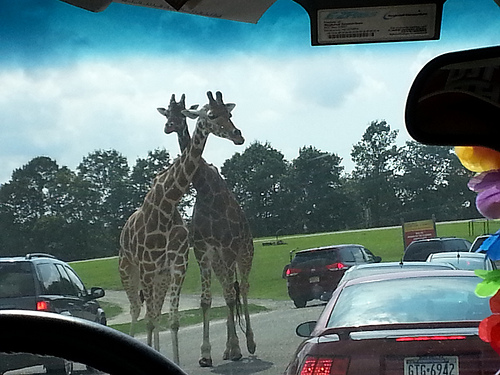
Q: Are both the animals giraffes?
A: Yes, all the animals are giraffes.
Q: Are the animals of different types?
A: No, all the animals are giraffes.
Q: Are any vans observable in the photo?
A: No, there are no vans.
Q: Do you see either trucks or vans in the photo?
A: No, there are no vans or trucks.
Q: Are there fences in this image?
A: No, there are no fences.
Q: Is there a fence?
A: No, there are no fences.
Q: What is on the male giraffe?
A: The spots are on the giraffe.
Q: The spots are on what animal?
A: The spots are on the giraffe.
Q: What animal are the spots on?
A: The spots are on the giraffe.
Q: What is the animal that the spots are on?
A: The animal is a giraffe.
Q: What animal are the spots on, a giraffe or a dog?
A: The spots are on a giraffe.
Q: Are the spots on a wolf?
A: No, the spots are on the giraffe.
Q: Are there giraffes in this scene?
A: Yes, there is a giraffe.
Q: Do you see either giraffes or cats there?
A: Yes, there is a giraffe.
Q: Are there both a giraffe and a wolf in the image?
A: No, there is a giraffe but no wolves.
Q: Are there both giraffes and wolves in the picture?
A: No, there is a giraffe but no wolves.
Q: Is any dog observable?
A: No, there are no dogs.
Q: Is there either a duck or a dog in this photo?
A: No, there are no dogs or ducks.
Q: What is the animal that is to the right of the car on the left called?
A: The animal is a giraffe.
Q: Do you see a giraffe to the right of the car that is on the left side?
A: Yes, there is a giraffe to the right of the car.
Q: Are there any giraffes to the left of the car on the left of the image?
A: No, the giraffe is to the right of the car.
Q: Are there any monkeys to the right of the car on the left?
A: No, there is a giraffe to the right of the car.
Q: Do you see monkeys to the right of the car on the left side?
A: No, there is a giraffe to the right of the car.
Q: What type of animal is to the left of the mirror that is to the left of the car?
A: The animal is a giraffe.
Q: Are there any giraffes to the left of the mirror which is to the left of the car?
A: Yes, there is a giraffe to the left of the mirror.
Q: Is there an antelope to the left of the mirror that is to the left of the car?
A: No, there is a giraffe to the left of the mirror.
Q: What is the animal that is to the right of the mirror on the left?
A: The animal is a giraffe.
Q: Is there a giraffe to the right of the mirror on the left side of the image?
A: Yes, there is a giraffe to the right of the mirror.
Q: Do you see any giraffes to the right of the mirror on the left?
A: Yes, there is a giraffe to the right of the mirror.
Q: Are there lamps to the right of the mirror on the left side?
A: No, there is a giraffe to the right of the mirror.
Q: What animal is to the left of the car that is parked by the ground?
A: The animal is a giraffe.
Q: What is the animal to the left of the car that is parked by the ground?
A: The animal is a giraffe.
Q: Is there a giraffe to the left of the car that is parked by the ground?
A: Yes, there is a giraffe to the left of the car.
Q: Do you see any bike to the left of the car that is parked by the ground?
A: No, there is a giraffe to the left of the car.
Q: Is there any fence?
A: No, there are no fences.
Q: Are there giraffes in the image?
A: Yes, there is a giraffe.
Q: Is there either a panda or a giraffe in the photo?
A: Yes, there is a giraffe.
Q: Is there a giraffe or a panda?
A: Yes, there is a giraffe.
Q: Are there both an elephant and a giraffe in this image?
A: No, there is a giraffe but no elephants.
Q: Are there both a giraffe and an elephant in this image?
A: No, there is a giraffe but no elephants.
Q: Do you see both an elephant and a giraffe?
A: No, there is a giraffe but no elephants.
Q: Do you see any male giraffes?
A: Yes, there is a male giraffe.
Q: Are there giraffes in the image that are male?
A: Yes, there is a giraffe that is male.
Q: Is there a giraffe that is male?
A: Yes, there is a giraffe that is male.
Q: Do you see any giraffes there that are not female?
A: Yes, there is a male giraffe.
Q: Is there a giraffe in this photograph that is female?
A: Yes, there is a female giraffe.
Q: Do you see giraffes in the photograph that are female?
A: Yes, there is a giraffe that is female.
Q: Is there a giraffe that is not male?
A: Yes, there is a female giraffe.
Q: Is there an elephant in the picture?
A: No, there are no elephants.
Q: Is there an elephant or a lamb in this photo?
A: No, there are no elephants or lambs.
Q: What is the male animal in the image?
A: The animal is a giraffe.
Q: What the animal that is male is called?
A: The animal is a giraffe.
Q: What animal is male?
A: The animal is a giraffe.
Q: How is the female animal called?
A: The animal is a giraffe.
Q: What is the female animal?
A: The animal is a giraffe.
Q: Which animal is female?
A: The animal is a giraffe.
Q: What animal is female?
A: The animal is a giraffe.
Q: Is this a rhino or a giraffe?
A: This is a giraffe.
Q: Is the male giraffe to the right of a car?
A: No, the giraffe is to the left of a car.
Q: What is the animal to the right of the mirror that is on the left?
A: The animal is a giraffe.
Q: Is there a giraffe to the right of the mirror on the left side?
A: Yes, there is a giraffe to the right of the mirror.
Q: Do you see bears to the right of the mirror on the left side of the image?
A: No, there is a giraffe to the right of the mirror.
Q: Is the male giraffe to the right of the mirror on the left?
A: Yes, the giraffe is to the right of the mirror.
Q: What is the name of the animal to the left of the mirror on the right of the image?
A: The animal is a giraffe.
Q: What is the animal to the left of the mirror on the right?
A: The animal is a giraffe.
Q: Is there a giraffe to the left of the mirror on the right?
A: Yes, there is a giraffe to the left of the mirror.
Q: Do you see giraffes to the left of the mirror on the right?
A: Yes, there is a giraffe to the left of the mirror.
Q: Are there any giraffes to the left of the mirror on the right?
A: Yes, there is a giraffe to the left of the mirror.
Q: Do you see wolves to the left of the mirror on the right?
A: No, there is a giraffe to the left of the mirror.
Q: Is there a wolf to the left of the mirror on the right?
A: No, there is a giraffe to the left of the mirror.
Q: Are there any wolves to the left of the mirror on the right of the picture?
A: No, there is a giraffe to the left of the mirror.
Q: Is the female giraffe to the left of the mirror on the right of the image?
A: Yes, the giraffe is to the left of the mirror.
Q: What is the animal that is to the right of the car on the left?
A: The animal is a giraffe.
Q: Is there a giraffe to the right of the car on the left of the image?
A: Yes, there is a giraffe to the right of the car.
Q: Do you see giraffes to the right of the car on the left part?
A: Yes, there is a giraffe to the right of the car.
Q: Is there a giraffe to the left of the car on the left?
A: No, the giraffe is to the right of the car.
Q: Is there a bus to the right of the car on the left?
A: No, there is a giraffe to the right of the car.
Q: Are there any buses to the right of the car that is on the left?
A: No, there is a giraffe to the right of the car.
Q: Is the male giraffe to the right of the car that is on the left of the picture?
A: Yes, the giraffe is to the right of the car.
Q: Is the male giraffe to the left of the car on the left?
A: No, the giraffe is to the right of the car.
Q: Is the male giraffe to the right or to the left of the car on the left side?
A: The giraffe is to the right of the car.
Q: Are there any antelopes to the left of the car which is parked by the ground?
A: No, there is a giraffe to the left of the car.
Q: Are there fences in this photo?
A: No, there are no fences.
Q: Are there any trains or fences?
A: No, there are no fences or trains.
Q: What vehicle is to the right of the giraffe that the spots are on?
A: The vehicle is a car.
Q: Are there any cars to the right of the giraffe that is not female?
A: Yes, there is a car to the right of the giraffe.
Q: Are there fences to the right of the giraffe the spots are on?
A: No, there is a car to the right of the giraffe.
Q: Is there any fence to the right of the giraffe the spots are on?
A: No, there is a car to the right of the giraffe.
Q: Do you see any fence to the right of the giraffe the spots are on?
A: No, there is a car to the right of the giraffe.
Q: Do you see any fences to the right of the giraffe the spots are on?
A: No, there is a car to the right of the giraffe.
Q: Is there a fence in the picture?
A: No, there are no fences.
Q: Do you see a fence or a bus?
A: No, there are no fences or buses.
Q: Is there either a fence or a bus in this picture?
A: No, there are no fences or buses.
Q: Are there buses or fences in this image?
A: No, there are no fences or buses.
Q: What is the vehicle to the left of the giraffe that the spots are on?
A: The vehicle is a car.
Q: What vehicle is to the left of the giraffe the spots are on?
A: The vehicle is a car.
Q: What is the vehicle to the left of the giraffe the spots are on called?
A: The vehicle is a car.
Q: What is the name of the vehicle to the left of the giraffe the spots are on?
A: The vehicle is a car.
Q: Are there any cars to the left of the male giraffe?
A: Yes, there is a car to the left of the giraffe.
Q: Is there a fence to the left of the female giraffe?
A: No, there is a car to the left of the giraffe.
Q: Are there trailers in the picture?
A: No, there are no trailers.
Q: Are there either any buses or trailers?
A: No, there are no trailers or buses.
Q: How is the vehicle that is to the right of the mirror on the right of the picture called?
A: The vehicle is a car.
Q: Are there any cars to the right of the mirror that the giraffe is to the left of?
A: Yes, there is a car to the right of the mirror.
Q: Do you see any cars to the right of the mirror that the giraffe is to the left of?
A: Yes, there is a car to the right of the mirror.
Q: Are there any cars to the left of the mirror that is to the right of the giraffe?
A: No, the car is to the right of the mirror.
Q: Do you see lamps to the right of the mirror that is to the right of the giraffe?
A: No, there is a car to the right of the mirror.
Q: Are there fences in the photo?
A: No, there are no fences.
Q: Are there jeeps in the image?
A: No, there are no jeeps.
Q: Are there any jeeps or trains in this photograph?
A: No, there are no jeeps or trains.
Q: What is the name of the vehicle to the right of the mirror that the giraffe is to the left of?
A: The vehicle is a car.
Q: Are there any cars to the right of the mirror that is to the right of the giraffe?
A: Yes, there is a car to the right of the mirror.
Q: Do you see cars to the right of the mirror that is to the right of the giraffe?
A: Yes, there is a car to the right of the mirror.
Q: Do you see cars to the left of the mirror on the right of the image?
A: No, the car is to the right of the mirror.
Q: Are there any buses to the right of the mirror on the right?
A: No, there is a car to the right of the mirror.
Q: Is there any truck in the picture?
A: No, there are no trucks.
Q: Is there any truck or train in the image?
A: No, there are no trucks or trains.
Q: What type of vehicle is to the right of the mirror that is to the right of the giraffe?
A: The vehicle is a car.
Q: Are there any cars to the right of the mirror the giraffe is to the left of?
A: Yes, there is a car to the right of the mirror.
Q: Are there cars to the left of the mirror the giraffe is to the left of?
A: No, the car is to the right of the mirror.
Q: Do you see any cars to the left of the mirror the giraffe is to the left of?
A: No, the car is to the right of the mirror.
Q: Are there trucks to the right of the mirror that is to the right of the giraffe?
A: No, there is a car to the right of the mirror.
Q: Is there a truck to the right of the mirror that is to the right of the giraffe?
A: No, there is a car to the right of the mirror.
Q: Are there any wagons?
A: No, there are no wagons.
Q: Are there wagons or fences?
A: No, there are no wagons or fences.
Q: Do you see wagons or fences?
A: No, there are no wagons or fences.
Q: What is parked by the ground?
A: The car is parked by the ground.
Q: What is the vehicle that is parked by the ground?
A: The vehicle is a car.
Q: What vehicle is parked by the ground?
A: The vehicle is a car.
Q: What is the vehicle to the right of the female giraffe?
A: The vehicle is a car.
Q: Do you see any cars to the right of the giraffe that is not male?
A: Yes, there is a car to the right of the giraffe.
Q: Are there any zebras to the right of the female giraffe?
A: No, there is a car to the right of the giraffe.